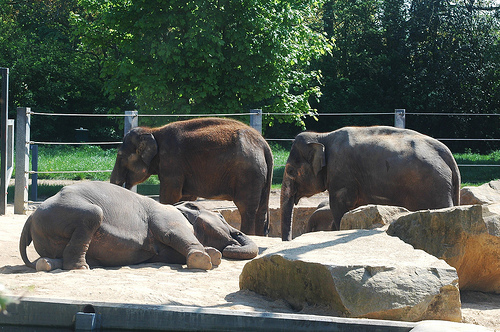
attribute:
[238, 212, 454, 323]
rocks — some 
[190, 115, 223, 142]
hair — elephant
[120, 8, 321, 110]
tree — leafy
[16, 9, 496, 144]
trees — some 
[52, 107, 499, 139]
fence — wire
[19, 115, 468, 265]
eephants — three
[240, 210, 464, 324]
rock — grey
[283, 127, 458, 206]
elephant — big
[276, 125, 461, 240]
animal — resting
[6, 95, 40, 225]
brick — concrete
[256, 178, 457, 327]
rocks — big